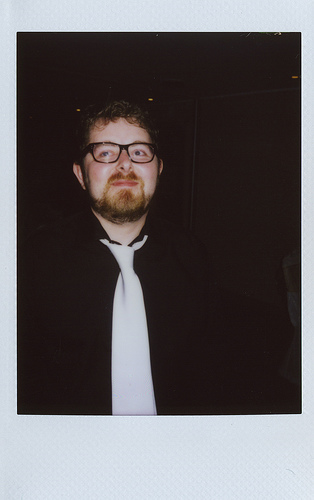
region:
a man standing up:
[47, 64, 270, 388]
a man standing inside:
[34, 71, 276, 389]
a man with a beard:
[38, 75, 215, 258]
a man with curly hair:
[51, 49, 189, 254]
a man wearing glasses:
[68, 63, 189, 255]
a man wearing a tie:
[35, 55, 248, 389]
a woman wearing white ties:
[41, 80, 267, 413]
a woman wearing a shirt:
[47, 67, 235, 340]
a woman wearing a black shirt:
[39, 93, 312, 389]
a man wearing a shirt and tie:
[33, 98, 312, 412]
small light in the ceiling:
[142, 92, 162, 102]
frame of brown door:
[180, 118, 206, 191]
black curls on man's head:
[90, 102, 139, 121]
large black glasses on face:
[80, 123, 184, 173]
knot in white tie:
[99, 235, 152, 268]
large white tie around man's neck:
[96, 245, 162, 371]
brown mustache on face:
[107, 170, 149, 184]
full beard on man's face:
[83, 186, 166, 227]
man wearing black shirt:
[158, 266, 196, 326]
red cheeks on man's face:
[91, 168, 108, 192]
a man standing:
[31, 76, 313, 406]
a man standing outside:
[32, 59, 311, 481]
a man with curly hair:
[29, 59, 273, 281]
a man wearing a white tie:
[41, 77, 308, 417]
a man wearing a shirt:
[31, 86, 260, 392]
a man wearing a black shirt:
[37, 57, 285, 388]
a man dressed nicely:
[16, 66, 232, 469]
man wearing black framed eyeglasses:
[37, 91, 241, 416]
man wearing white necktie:
[39, 102, 238, 424]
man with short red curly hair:
[48, 90, 231, 417]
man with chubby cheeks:
[33, 91, 242, 418]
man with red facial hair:
[41, 84, 234, 416]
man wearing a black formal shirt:
[30, 86, 240, 417]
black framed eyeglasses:
[73, 135, 165, 167]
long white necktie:
[91, 234, 170, 415]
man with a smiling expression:
[34, 87, 228, 415]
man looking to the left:
[35, 86, 234, 414]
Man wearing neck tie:
[67, 103, 176, 371]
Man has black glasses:
[80, 132, 171, 168]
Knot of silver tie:
[105, 242, 151, 273]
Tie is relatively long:
[105, 260, 172, 419]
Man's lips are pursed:
[112, 177, 146, 194]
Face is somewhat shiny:
[120, 159, 146, 174]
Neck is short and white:
[98, 211, 148, 248]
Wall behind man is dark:
[177, 147, 295, 304]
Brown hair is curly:
[84, 88, 159, 140]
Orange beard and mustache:
[100, 171, 152, 224]